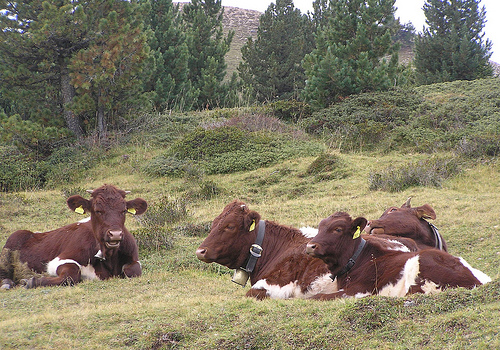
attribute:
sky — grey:
[176, 0, 499, 63]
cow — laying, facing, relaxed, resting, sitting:
[2, 185, 147, 291]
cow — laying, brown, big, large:
[197, 201, 420, 302]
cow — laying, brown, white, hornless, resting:
[310, 210, 489, 302]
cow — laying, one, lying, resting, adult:
[364, 194, 446, 252]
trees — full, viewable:
[6, 2, 235, 105]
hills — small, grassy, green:
[141, 79, 494, 158]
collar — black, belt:
[238, 216, 267, 276]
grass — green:
[6, 129, 499, 344]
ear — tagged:
[350, 217, 367, 230]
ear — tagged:
[242, 210, 261, 230]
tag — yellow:
[72, 205, 85, 214]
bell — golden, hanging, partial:
[232, 266, 249, 285]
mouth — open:
[104, 237, 125, 247]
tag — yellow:
[353, 225, 360, 238]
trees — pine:
[414, 1, 494, 86]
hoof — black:
[23, 274, 37, 289]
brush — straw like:
[369, 136, 475, 191]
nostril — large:
[201, 247, 207, 254]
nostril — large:
[312, 244, 317, 252]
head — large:
[195, 199, 260, 272]